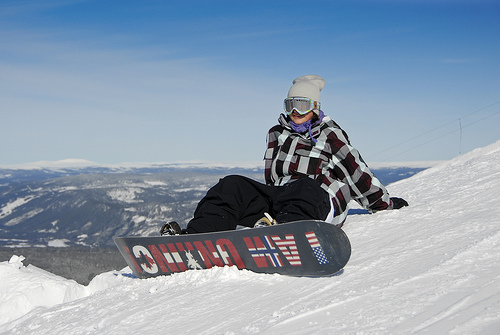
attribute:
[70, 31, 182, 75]
sky — Blue 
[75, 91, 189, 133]
clouds — thin, white 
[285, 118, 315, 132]
tie — purple 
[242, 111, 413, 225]
shirt — Checkered 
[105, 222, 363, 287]
snowboard — Black 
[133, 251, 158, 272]
maple leaf — design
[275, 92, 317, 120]
goggle — blue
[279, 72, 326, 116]
knitted cap — slouchy , knitted 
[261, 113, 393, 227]
sweater — plaid 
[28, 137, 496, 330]
snowy slope — snowy  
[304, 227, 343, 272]
design — Stars , stripes 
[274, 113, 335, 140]
scarf — purple 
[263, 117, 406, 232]
coat — blue , brown 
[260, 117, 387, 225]
shirt — plaid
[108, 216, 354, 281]
snowboard — black 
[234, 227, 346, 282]
snowboard — black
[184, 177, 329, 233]
pants — black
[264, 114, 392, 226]
shirt — red, white, black, checked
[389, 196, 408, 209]
mitten — black 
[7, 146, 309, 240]
peaks — Snowy 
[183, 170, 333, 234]
pants — black 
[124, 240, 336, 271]
writing — red, white, blue 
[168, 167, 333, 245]
pants — black  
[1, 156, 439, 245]
snow — patchy 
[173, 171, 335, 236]
pants — black 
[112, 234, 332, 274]
writing — red, white, blue